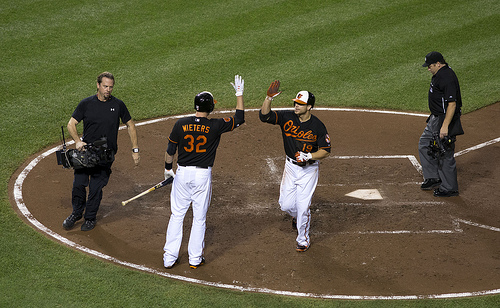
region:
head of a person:
[179, 88, 216, 116]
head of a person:
[290, 85, 327, 122]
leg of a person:
[157, 171, 188, 258]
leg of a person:
[180, 191, 220, 262]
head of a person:
[83, 59, 117, 109]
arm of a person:
[60, 103, 82, 150]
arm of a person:
[111, 103, 145, 145]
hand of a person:
[129, 156, 146, 165]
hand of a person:
[66, 140, 99, 156]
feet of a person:
[60, 205, 79, 225]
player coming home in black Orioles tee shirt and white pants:
[267, 80, 329, 252]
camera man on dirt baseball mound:
[62, 70, 148, 230]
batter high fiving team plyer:
[117, 70, 249, 275]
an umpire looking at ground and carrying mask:
[416, 45, 463, 195]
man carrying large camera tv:
[55, 69, 145, 231]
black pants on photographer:
[65, 145, 120, 220]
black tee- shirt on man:
[70, 91, 135, 143]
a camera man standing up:
[44, 74, 144, 227]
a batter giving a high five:
[157, 81, 251, 279]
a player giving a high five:
[262, 75, 329, 260]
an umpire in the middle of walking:
[399, 51, 476, 200]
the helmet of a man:
[186, 86, 216, 120]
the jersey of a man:
[154, 100, 246, 166]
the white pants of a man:
[171, 163, 208, 259]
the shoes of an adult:
[156, 243, 209, 280]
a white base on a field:
[314, 177, 388, 217]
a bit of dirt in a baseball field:
[349, 217, 451, 307]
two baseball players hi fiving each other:
[155, 70, 333, 273]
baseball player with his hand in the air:
[256, 77, 335, 254]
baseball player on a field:
[257, 75, 335, 249]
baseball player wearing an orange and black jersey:
[256, 76, 336, 253]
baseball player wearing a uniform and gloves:
[255, 76, 333, 253]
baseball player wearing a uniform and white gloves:
[118, 73, 248, 273]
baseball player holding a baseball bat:
[118, 72, 249, 272]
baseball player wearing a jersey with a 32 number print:
[120, 70, 248, 271]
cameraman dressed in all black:
[53, 71, 142, 233]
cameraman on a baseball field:
[48, 68, 142, 233]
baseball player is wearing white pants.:
[166, 161, 208, 270]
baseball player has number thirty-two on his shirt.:
[181, 131, 208, 158]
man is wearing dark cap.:
[423, 50, 444, 67]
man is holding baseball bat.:
[118, 172, 180, 206]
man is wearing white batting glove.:
[228, 73, 245, 98]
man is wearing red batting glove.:
[266, 75, 282, 102]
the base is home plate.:
[341, 176, 384, 210]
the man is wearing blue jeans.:
[420, 114, 461, 199]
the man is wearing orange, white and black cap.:
[293, 88, 315, 110]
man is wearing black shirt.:
[71, 93, 129, 152]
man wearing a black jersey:
[163, 112, 220, 164]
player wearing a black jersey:
[265, 103, 340, 163]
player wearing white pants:
[166, 163, 214, 266]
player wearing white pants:
[273, 154, 319, 248]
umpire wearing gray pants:
[415, 111, 467, 193]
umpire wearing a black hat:
[421, 51, 443, 74]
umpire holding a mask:
[419, 124, 454, 159]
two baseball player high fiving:
[160, 71, 336, 280]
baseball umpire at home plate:
[335, 46, 467, 206]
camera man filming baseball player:
[52, 56, 249, 277]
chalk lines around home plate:
[271, 144, 465, 240]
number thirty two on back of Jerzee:
[161, 70, 253, 170]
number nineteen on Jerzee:
[284, 123, 319, 159]